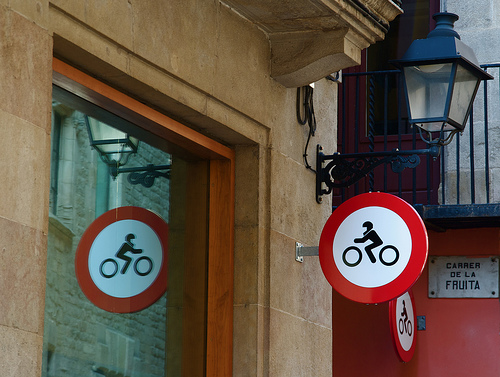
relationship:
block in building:
[266, 147, 333, 249] [0, 1, 403, 377]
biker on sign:
[342, 219, 399, 270] [319, 190, 428, 306]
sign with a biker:
[319, 190, 428, 306] [342, 219, 399, 270]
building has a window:
[0, 1, 403, 377] [43, 53, 237, 376]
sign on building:
[319, 190, 428, 306] [0, 1, 403, 377]